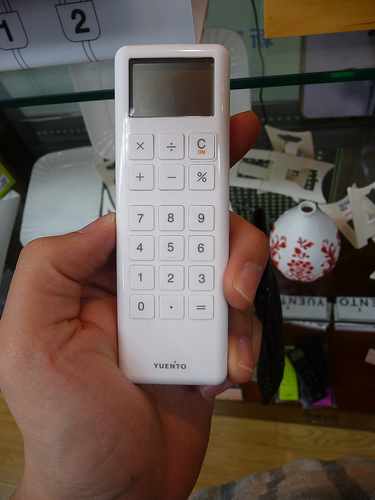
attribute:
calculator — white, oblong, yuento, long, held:
[100, 40, 232, 394]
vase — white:
[265, 188, 342, 285]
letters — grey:
[5, 1, 106, 65]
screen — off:
[128, 59, 214, 114]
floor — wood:
[2, 419, 364, 498]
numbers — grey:
[4, 10, 90, 46]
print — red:
[267, 227, 335, 276]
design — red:
[284, 234, 318, 289]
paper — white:
[70, 4, 192, 62]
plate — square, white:
[17, 140, 104, 255]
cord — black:
[244, 3, 273, 115]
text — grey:
[0, 8, 119, 87]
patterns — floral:
[270, 244, 339, 267]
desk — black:
[25, 86, 374, 324]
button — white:
[182, 130, 220, 164]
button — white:
[132, 138, 153, 157]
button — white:
[157, 136, 186, 159]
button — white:
[159, 162, 186, 195]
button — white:
[188, 164, 214, 190]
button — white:
[128, 236, 156, 261]